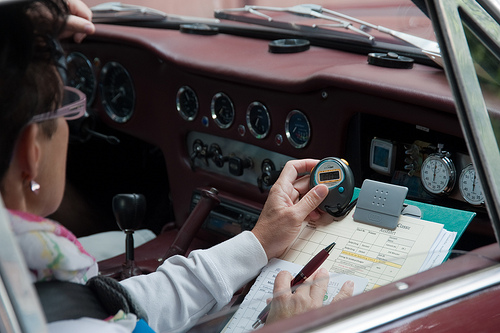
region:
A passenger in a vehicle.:
[3, 11, 330, 330]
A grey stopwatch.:
[299, 156, 352, 219]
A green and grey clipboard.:
[289, 160, 479, 277]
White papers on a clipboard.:
[220, 200, 448, 332]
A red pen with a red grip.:
[250, 235, 337, 328]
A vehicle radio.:
[192, 196, 253, 232]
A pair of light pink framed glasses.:
[25, 85, 90, 120]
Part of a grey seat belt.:
[26, 280, 106, 325]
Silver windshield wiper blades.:
[86, 0, 442, 60]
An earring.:
[25, 173, 45, 199]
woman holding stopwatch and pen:
[0, 0, 364, 296]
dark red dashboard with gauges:
[94, 17, 499, 217]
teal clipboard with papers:
[242, 157, 481, 294]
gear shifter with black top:
[102, 185, 163, 272]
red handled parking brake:
[164, 177, 239, 262]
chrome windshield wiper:
[213, 2, 460, 69]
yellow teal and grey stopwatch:
[305, 149, 365, 212]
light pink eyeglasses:
[20, 77, 92, 128]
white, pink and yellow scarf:
[6, 205, 111, 284]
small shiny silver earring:
[17, 174, 50, 196]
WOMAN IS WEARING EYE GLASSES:
[72, 98, 82, 110]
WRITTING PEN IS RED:
[306, 258, 313, 274]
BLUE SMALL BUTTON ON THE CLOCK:
[340, 186, 346, 193]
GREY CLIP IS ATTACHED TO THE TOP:
[360, 184, 397, 224]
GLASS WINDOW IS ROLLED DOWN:
[360, 275, 369, 282]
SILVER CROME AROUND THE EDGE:
[452, 41, 461, 75]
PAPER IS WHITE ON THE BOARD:
[417, 241, 428, 249]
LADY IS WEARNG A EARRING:
[30, 177, 36, 196]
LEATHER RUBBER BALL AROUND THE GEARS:
[115, 190, 137, 230]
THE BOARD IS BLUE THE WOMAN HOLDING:
[453, 211, 467, 228]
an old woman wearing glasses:
[5, 5, 350, 332]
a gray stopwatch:
[290, 140, 375, 220]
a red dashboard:
[98, 15, 496, 137]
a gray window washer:
[208, 2, 480, 85]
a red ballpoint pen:
[250, 230, 338, 331]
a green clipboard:
[217, 166, 480, 331]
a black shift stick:
[107, 187, 152, 278]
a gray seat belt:
[25, 264, 152, 331]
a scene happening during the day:
[5, 0, 497, 329]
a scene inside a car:
[10, 2, 494, 314]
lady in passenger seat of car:
[11, 17, 486, 331]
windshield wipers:
[95, 4, 433, 59]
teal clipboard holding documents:
[205, 165, 485, 325]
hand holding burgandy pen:
[220, 239, 375, 329]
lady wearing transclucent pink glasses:
[2, 74, 94, 136]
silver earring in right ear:
[19, 121, 52, 206]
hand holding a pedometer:
[287, 140, 363, 243]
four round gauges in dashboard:
[150, 84, 332, 151]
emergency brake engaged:
[154, 171, 236, 263]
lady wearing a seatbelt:
[4, 79, 176, 331]